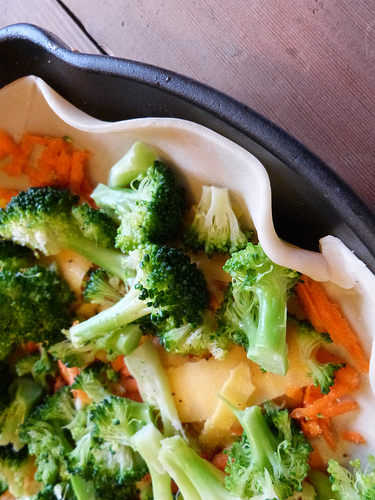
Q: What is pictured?
A: Vegetables.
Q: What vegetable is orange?
A: Carrots.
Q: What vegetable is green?
A: Broccoli.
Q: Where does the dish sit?
A: On a table.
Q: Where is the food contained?
A: In iron dish.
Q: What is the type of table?
A: Brown wood.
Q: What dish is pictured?
A: A broccoli and carrot side dish.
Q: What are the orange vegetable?
A: Carrot.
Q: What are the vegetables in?
A: Raw pie crust.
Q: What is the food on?
A: Black pan.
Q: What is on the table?
A: A skillet.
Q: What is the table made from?
A: Wood.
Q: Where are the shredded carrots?
A: Under the broccoli.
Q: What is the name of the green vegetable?
A: Broccoli.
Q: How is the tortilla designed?
A: Scalloped.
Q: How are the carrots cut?
A: Julienne.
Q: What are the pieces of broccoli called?
A: Florets.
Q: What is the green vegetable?
A: Broccoli.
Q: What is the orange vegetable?
A: Carrots.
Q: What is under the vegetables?
A: An uncooked crust.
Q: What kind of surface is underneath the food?
A: A wooden surface.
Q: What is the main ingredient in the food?
A: Broccoli.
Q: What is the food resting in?
A: A cast iron skillet.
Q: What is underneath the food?
A: A wooden surface.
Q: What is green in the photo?
A: Broccoli.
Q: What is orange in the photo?
A: Carrots.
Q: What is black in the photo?
A: The pan.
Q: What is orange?
A: Carrots.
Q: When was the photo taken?
A: Daytime.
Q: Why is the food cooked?
A: It is meal time.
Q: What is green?
A: Broccoli.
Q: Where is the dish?
A: On the table.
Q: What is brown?
A: The table.